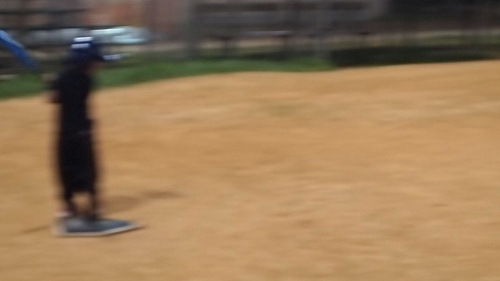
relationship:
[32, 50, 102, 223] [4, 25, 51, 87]
batter holding bat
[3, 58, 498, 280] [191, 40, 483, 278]
dirt lying on field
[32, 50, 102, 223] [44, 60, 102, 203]
batter wearing clothing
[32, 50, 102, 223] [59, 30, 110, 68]
batter wearing helmet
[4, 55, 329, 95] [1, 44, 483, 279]
grass growing in field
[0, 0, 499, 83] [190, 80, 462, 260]
fence standing alongside baseball field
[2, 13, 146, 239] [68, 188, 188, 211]
batter casting shadow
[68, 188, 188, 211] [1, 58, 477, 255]
shadow casting on ground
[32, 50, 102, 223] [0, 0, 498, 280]
batter standing on field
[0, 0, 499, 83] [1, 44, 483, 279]
fence standing alongside field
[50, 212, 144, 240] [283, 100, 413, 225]
base lying on dirt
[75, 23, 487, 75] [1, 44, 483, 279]
fence standing alongside field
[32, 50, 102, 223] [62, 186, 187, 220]
batter casting shadow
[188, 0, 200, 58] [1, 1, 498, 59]
pole on fence